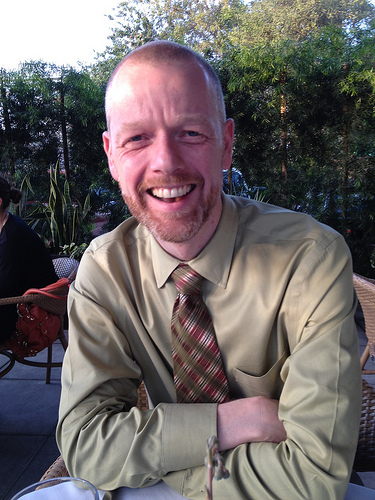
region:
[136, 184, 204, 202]
white teeth on man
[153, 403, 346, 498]
arms crossed against chest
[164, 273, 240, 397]
red and gray striped tie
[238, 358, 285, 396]
pocket on the shirt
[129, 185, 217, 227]
beard on the face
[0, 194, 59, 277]
person sitting in a chair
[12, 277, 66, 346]
red item over the chair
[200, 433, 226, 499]
rope by the arms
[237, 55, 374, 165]
trees in back of man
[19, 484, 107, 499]
napkin by the glass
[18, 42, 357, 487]
man sitting in chairt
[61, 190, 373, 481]
man wearing green shirt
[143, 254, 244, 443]
man wearing plaid tie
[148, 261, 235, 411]
tie is red and green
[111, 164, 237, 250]
man with brown beard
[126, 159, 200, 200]
man with brown mustache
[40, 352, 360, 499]
man has arms folded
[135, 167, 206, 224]
man smiling with mouth open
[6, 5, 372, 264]
lush greenery in background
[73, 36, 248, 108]
man with brown hair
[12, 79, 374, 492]
picture taken outdoors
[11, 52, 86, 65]
picture taken during the day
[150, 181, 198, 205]
a man is smiling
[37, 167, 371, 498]
a man is sitting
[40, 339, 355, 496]
a man has his arms folded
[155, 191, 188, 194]
the man's teeth are white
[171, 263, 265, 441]
the man wears a tie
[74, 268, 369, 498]
a man wears a long sleeved shirt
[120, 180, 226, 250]
the man has a beard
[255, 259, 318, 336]
the shirt is green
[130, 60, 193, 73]
hairline on mans head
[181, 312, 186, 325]
burgandy plaid on tie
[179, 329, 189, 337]
green plaid on tie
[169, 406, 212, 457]
left cuff of shirt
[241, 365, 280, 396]
pocket of green shirt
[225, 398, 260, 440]
top of mans hand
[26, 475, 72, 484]
rim of glass on table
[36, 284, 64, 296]
bag on back of chair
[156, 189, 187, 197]
teeth in mans mouth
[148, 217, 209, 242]
hair on mans chin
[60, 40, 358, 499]
man in a green shirt and tie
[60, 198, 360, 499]
an olive green dress shirt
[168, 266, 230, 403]
a red and green plaid tie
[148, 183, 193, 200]
the man's smile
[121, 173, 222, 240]
the smiling man's beard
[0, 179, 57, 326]
woman in black at the next table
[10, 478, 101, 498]
edge of a clear water glass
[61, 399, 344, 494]
arms folded and on the table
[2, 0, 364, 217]
several trees in the background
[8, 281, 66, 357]
a red seat cushion